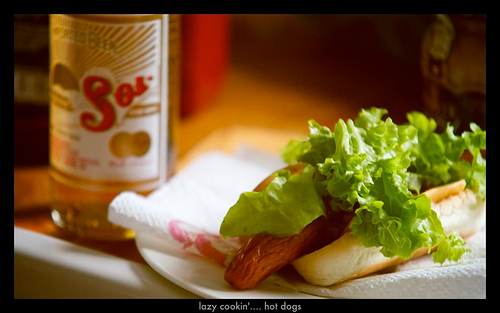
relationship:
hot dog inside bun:
[220, 207, 346, 290] [205, 141, 495, 298]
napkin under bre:
[84, 130, 489, 298] [205, 141, 495, 298]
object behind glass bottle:
[186, 13, 239, 118] [39, 12, 186, 251]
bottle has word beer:
[39, 12, 186, 251] [124, 98, 162, 120]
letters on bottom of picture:
[194, 299, 305, 313] [1, 3, 498, 313]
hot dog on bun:
[220, 207, 346, 290] [205, 141, 495, 298]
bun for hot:
[205, 141, 495, 298] [220, 207, 346, 290]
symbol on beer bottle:
[100, 125, 157, 167] [39, 12, 186, 251]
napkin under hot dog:
[84, 130, 489, 298] [220, 207, 346, 290]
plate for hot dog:
[205, 141, 495, 298] [220, 207, 346, 290]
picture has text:
[1, 3, 498, 313] [194, 299, 305, 313]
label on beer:
[39, 15, 171, 191] [39, 12, 186, 251]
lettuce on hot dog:
[210, 99, 489, 274] [220, 207, 346, 290]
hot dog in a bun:
[220, 207, 346, 290] [205, 141, 495, 298]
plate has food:
[84, 130, 489, 298] [210, 99, 489, 274]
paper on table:
[12, 210, 160, 293] [19, 65, 489, 312]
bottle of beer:
[39, 12, 186, 251] [73, 67, 154, 141]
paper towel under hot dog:
[84, 130, 489, 298] [220, 207, 346, 290]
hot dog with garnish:
[220, 207, 346, 290] [210, 99, 489, 274]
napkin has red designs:
[84, 130, 489, 298] [165, 206, 239, 270]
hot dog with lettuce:
[220, 207, 346, 290] [210, 99, 489, 274]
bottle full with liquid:
[39, 12, 186, 251] [51, 15, 175, 238]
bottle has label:
[39, 12, 186, 251] [39, 15, 171, 191]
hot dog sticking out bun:
[220, 207, 346, 290] [205, 141, 495, 298]